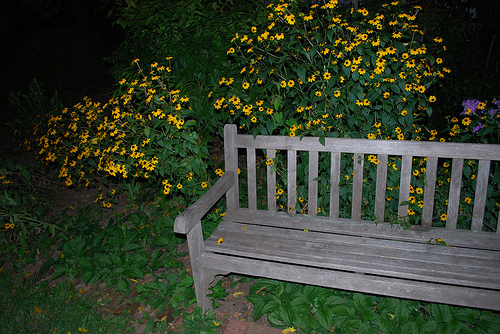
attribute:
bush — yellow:
[237, 4, 449, 119]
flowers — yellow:
[210, 2, 449, 139]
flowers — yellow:
[22, 51, 189, 203]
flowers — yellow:
[51, 72, 195, 177]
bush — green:
[139, 20, 229, 94]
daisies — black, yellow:
[16, 49, 194, 207]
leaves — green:
[6, 195, 188, 314]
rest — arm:
[172, 176, 235, 242]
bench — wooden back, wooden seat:
[171, 114, 498, 320]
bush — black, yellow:
[225, 4, 435, 128]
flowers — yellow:
[205, 23, 447, 134]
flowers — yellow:
[289, 15, 456, 105]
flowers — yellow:
[34, 52, 184, 193]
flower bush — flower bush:
[198, 3, 485, 144]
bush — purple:
[189, 14, 491, 164]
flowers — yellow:
[24, 58, 209, 203]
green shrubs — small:
[6, 199, 192, 332]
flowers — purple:
[387, 55, 497, 147]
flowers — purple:
[455, 94, 484, 129]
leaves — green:
[145, 117, 204, 175]